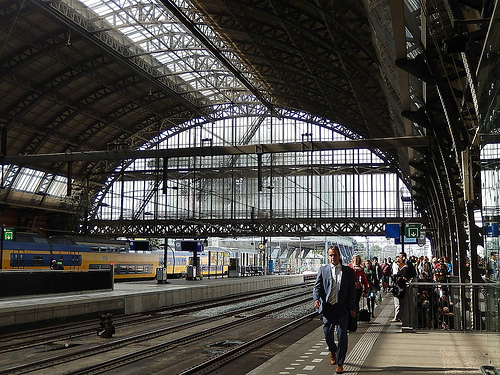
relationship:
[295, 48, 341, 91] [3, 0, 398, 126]
section of dome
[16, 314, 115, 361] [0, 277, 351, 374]
section of rail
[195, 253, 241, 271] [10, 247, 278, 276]
section of train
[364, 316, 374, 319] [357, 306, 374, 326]
part of bag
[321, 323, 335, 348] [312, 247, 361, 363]
leg of man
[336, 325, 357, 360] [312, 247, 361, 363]
leg of man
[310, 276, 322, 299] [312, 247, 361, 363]
arm of man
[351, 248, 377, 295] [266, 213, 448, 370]
woman on top of station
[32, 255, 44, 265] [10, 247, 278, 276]
window of train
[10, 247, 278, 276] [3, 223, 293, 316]
train in substation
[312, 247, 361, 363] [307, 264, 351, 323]
man wearing suit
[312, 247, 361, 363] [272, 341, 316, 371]
man on sidewalk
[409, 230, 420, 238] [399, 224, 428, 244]
arrow on signs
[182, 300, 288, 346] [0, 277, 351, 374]
sets of rail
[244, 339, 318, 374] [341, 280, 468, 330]
platform for loading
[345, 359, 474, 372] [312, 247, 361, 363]
shadow from man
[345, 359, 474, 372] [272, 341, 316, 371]
shadow on sidewalk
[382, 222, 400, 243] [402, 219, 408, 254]
flag hanging from pole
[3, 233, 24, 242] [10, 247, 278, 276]
light for train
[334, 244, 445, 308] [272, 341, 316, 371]
people on sidewalk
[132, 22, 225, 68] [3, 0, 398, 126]
lights on dome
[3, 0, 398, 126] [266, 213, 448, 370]
dome of station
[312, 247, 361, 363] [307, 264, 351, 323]
man in suit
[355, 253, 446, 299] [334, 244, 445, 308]
crowd of people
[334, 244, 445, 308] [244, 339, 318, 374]
people on platform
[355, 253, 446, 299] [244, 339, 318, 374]
crowd on platform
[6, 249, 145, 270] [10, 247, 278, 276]
windows on train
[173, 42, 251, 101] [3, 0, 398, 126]
skylights in dome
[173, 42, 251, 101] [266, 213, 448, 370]
skylights in station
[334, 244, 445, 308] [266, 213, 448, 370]
people in station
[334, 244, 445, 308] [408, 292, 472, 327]
people in stairwell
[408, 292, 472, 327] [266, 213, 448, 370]
stairwell in station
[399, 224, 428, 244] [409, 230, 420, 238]
signs with arrow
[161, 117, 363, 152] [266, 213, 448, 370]
bars over station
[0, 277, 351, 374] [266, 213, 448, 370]
rail in station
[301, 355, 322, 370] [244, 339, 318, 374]
squares on platform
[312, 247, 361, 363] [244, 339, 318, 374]
man on platform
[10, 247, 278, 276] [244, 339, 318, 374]
train at platform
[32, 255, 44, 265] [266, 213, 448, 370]
window of station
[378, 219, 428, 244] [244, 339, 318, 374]
signs above platform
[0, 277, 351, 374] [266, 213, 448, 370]
rail at station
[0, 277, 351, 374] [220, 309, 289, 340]
rail for rail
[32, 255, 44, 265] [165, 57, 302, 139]
window of dome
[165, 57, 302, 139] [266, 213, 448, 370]
dome of station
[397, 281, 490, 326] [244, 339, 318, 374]
barricade on platform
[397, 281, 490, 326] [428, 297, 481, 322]
barricade by stairs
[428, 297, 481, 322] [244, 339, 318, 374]
stairs on platform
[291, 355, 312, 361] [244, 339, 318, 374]
lines on ground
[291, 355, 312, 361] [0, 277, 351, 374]
lines near rail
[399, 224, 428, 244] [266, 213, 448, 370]
signs on side of station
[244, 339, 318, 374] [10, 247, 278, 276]
platform for train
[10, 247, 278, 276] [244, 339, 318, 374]
train next to platform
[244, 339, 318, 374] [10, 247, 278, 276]
platform next to train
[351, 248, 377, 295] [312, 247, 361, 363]
woman behind man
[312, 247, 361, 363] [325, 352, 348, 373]
man wearing shoes